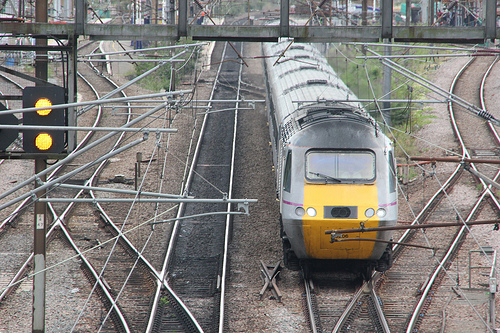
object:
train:
[261, 16, 398, 273]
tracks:
[144, 16, 247, 333]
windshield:
[304, 151, 375, 180]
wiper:
[309, 171, 342, 182]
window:
[304, 150, 375, 184]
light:
[306, 207, 317, 218]